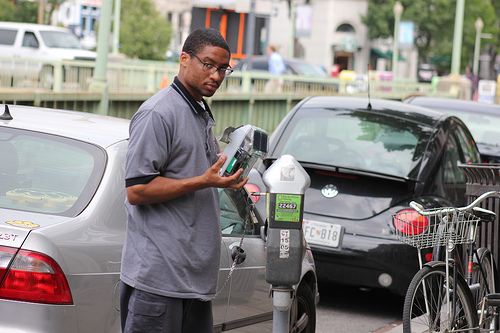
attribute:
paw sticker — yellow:
[6, 215, 39, 231]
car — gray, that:
[1, 100, 322, 332]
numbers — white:
[278, 201, 297, 211]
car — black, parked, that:
[243, 89, 483, 301]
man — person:
[119, 26, 249, 332]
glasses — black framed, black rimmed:
[193, 51, 233, 80]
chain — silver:
[211, 190, 259, 296]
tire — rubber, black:
[400, 259, 478, 332]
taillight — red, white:
[2, 244, 75, 305]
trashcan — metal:
[457, 158, 499, 293]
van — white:
[1, 20, 98, 90]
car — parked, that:
[402, 92, 499, 182]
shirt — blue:
[267, 50, 285, 73]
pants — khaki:
[261, 73, 286, 94]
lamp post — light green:
[90, 0, 116, 91]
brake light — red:
[394, 209, 427, 235]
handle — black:
[230, 244, 247, 264]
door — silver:
[218, 180, 278, 332]